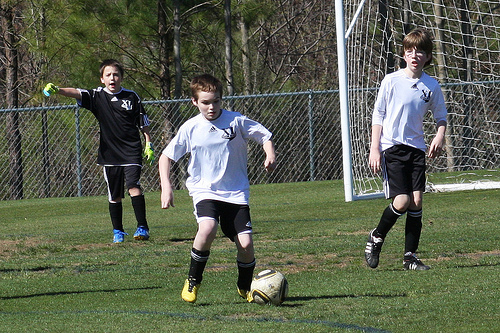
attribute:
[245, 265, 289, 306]
ball — white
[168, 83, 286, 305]
boy — yelling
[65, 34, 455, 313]
kids — wearing, young, playing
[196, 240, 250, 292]
socks — black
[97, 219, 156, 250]
shoes — blue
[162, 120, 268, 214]
shirt — white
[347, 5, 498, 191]
net — white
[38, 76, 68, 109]
gloves — yellow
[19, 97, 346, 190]
fence — chain link, chain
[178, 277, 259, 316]
shoes — yellow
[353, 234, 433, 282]
shoes — black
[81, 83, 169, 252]
uniform — black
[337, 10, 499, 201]
goal — white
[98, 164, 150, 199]
shorts — black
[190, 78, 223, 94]
hair — short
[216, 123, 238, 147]
logo — black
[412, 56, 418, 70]
mouth — open